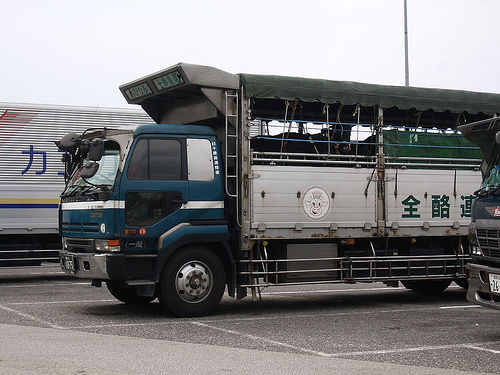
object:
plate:
[59, 253, 75, 271]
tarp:
[234, 72, 499, 134]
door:
[116, 137, 184, 234]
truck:
[53, 59, 498, 322]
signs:
[121, 79, 154, 101]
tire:
[158, 247, 228, 318]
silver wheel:
[174, 260, 215, 304]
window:
[122, 137, 190, 183]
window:
[121, 188, 186, 229]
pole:
[403, 0, 410, 87]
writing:
[17, 143, 50, 176]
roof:
[236, 70, 500, 118]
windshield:
[61, 131, 135, 195]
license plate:
[486, 272, 498, 297]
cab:
[57, 122, 234, 286]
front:
[52, 119, 134, 289]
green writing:
[398, 192, 424, 220]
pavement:
[4, 265, 493, 364]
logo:
[299, 186, 333, 221]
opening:
[189, 263, 196, 268]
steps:
[238, 277, 351, 288]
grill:
[56, 214, 108, 254]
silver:
[6, 110, 42, 148]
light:
[92, 238, 110, 253]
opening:
[178, 272, 184, 279]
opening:
[178, 289, 185, 296]